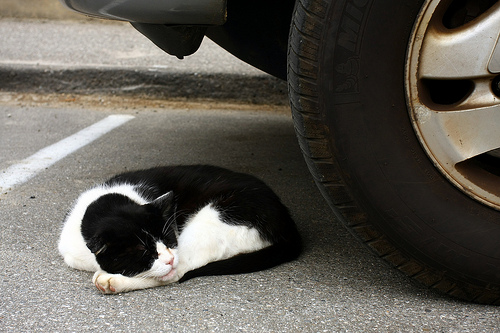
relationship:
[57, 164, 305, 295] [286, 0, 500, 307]
cat under tire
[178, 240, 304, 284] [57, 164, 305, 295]
tail under cat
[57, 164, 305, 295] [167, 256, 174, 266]
cat has nose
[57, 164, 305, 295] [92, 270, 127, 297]
cat has paw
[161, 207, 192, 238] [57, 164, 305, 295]
lash on cat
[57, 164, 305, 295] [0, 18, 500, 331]
cat on ground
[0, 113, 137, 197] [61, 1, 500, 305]
line under car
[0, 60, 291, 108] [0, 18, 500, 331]
curb on ground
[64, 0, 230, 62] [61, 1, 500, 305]
bumper on car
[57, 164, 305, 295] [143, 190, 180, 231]
cat has ear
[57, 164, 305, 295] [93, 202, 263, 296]
cat has leg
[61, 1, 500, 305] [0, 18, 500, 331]
car on ground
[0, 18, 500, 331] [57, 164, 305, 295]
ground below cat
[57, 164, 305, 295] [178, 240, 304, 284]
cat has tail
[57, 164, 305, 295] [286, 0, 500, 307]
cat by tire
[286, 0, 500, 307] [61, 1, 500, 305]
tire on car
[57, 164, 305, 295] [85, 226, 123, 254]
cat has ear